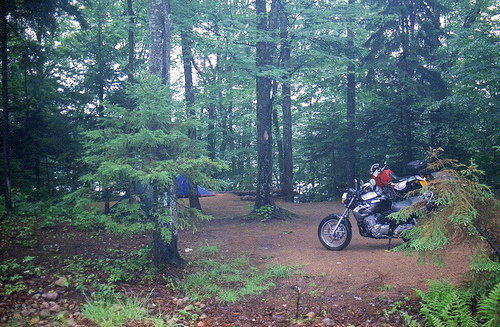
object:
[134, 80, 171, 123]
leaves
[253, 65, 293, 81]
leaves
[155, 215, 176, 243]
leaves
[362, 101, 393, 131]
leaves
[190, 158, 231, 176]
leaves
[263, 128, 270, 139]
bark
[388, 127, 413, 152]
ground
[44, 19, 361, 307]
scene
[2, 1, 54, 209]
trees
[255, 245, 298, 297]
ground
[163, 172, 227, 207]
blue tent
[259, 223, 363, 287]
ground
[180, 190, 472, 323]
ground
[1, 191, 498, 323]
ground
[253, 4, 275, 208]
trunk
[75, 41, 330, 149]
forest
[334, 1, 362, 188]
trees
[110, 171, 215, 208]
tent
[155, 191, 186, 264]
woods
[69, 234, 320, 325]
grass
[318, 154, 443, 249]
bike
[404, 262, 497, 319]
ferns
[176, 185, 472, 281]
bare earth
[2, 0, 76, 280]
trees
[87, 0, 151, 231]
trees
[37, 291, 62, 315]
stones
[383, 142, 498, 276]
plant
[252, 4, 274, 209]
tree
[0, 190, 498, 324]
sand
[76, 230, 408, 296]
ground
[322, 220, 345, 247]
part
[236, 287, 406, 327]
part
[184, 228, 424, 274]
patch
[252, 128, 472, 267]
beautiful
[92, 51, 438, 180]
sky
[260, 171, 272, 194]
moss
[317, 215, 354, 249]
front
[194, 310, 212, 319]
pebbles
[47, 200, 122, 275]
apart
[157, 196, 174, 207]
grey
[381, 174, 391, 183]
color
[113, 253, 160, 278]
apart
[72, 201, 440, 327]
color